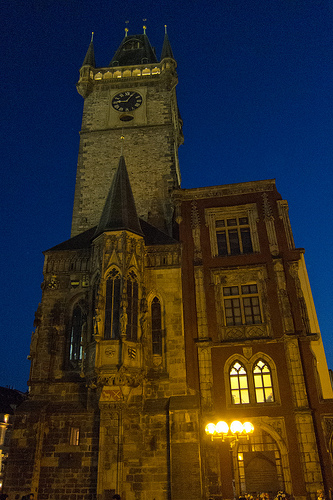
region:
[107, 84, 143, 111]
clock on the tower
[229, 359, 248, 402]
window on the building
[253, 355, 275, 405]
window on the building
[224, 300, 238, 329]
window on the building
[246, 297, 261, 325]
window on the building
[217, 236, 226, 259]
window on the building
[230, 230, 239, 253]
window on the building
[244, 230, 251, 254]
window on the building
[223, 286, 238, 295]
window on the building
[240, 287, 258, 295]
window on the building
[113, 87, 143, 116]
black and white clock in clock tower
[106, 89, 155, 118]
clock in clock tower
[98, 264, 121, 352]
window in brown colored old buidling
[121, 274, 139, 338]
window in brown colored old buidling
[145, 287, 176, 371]
window in brown colored old buidling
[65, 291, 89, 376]
window in brown colored old buidling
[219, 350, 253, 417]
window in brown colored old buidling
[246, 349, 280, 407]
window in brown colored old buidling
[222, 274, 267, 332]
window in brown colored old buidling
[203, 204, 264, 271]
window in brown colored old buidling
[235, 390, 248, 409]
pane in the window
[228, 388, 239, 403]
pane in the window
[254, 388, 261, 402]
pane in the window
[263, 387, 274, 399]
pane in the window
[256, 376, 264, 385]
pane in the window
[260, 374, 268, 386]
pane in the window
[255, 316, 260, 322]
pane in the window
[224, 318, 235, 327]
pane in the window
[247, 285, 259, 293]
pane in the window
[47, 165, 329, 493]
the brown building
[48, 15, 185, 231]
the tower above the building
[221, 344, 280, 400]
the windows are arched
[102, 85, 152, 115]
the clock on the tower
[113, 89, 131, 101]
the hands on the clock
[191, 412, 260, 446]
the lights in front of the building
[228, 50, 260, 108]
the blue night sky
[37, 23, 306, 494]
the building is old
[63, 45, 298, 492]
the building is brick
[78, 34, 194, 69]
the roof of the tower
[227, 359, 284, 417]
The light is on in the window.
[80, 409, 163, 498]
The building is made of brick.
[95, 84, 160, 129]
A clock on the top of the tower.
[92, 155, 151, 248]
A triangle shaped roof.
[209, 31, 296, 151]
It is dark outside.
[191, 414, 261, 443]
The lights in front of the building.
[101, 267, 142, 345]
Windows in front of the building.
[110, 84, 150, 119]
The face of the clock is black.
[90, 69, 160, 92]
The lights are on the top of building.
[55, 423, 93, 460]
A little window on the building.